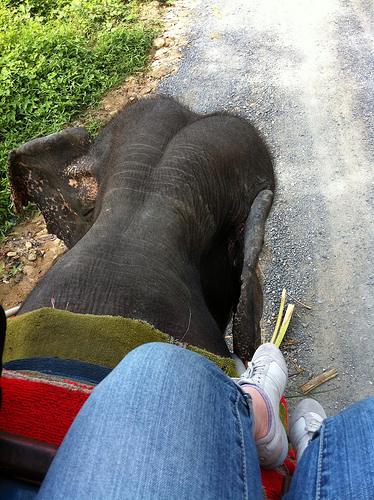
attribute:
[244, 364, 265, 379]
shoelaces — white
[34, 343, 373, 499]
person — sitting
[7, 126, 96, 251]
ear — huge, big, gray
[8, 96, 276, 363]
elephant — grey, big, gray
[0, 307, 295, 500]
rug — green, blue, red, colorful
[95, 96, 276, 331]
head — large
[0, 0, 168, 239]
grass — in left hand company, growing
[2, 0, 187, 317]
dirt — brown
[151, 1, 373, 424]
road — gravel, dirt, gray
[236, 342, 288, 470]
tennis shoe — white, part of a pair, for woman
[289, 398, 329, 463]
tennis shoe — white, part of a pair, for woman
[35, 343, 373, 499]
jeans — blue, denim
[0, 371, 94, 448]
stripe — red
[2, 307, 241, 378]
stripe — green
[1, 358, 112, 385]
stripe — blue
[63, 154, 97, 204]
area — light colored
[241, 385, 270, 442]
ankle — bare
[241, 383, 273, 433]
sock — low cut, gray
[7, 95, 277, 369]
skin — wrinkly